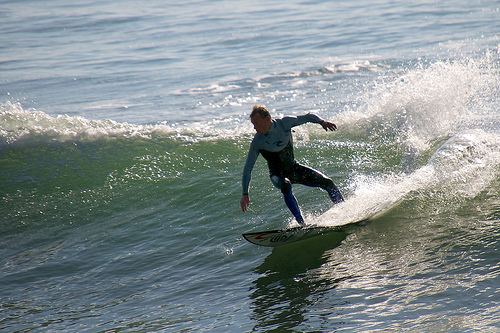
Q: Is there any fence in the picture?
A: No, there are no fences.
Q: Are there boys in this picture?
A: No, there are no boys.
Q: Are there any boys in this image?
A: No, there are no boys.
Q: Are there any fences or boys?
A: No, there are no boys or fences.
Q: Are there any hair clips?
A: No, there are no hair clips.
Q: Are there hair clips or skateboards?
A: No, there are no hair clips or skateboards.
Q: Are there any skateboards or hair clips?
A: No, there are no hair clips or skateboards.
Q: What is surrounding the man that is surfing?
A: The water is surrounding the man.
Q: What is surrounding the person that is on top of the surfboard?
A: The water is surrounding the man.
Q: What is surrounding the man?
A: The water is surrounding the man.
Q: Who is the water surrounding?
A: The water is surrounding the man.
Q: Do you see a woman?
A: No, there are no women.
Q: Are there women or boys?
A: No, there are no women or boys.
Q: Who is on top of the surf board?
A: The man is on top of the surf board.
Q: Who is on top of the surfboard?
A: The man is on top of the surf board.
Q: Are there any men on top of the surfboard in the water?
A: Yes, there is a man on top of the surfboard.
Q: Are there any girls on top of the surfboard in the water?
A: No, there is a man on top of the surfboard.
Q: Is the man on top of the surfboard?
A: Yes, the man is on top of the surfboard.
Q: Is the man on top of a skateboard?
A: No, the man is on top of the surfboard.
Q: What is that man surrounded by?
A: The man is surrounded by the water.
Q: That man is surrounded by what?
A: The man is surrounded by the water.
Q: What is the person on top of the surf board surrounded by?
A: The man is surrounded by the water.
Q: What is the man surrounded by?
A: The man is surrounded by the water.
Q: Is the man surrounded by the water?
A: Yes, the man is surrounded by the water.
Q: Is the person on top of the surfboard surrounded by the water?
A: Yes, the man is surrounded by the water.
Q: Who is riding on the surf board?
A: The man is riding on the surf board.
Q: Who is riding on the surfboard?
A: The man is riding on the surf board.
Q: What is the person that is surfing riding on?
A: The man is riding on the surfboard.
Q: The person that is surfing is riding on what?
A: The man is riding on the surfboard.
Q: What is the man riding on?
A: The man is riding on the surfboard.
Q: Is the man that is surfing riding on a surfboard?
A: Yes, the man is riding on a surfboard.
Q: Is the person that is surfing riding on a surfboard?
A: Yes, the man is riding on a surfboard.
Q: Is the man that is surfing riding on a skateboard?
A: No, the man is riding on a surfboard.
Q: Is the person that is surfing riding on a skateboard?
A: No, the man is riding on a surfboard.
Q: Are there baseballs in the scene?
A: No, there are no baseballs.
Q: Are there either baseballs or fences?
A: No, there are no baseballs or fences.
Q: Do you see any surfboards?
A: Yes, there is a surfboard.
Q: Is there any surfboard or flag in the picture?
A: Yes, there is a surfboard.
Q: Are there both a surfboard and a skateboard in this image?
A: No, there is a surfboard but no skateboards.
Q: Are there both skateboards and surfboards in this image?
A: No, there is a surfboard but no skateboards.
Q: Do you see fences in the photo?
A: No, there are no fences.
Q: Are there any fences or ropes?
A: No, there are no fences or ropes.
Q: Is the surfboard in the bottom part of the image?
A: Yes, the surfboard is in the bottom of the image.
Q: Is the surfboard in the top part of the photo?
A: No, the surfboard is in the bottom of the image.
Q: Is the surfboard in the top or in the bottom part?
A: The surfboard is in the bottom of the image.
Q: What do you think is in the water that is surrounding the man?
A: The surfboard is in the water.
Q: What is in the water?
A: The surfboard is in the water.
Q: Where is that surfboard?
A: The surfboard is in the water.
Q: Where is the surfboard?
A: The surfboard is in the water.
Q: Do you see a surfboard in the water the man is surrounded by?
A: Yes, there is a surfboard in the water.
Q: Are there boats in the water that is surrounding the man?
A: No, there is a surfboard in the water.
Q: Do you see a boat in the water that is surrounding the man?
A: No, there is a surfboard in the water.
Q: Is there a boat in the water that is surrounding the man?
A: No, there is a surfboard in the water.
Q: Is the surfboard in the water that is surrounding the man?
A: Yes, the surfboard is in the water.